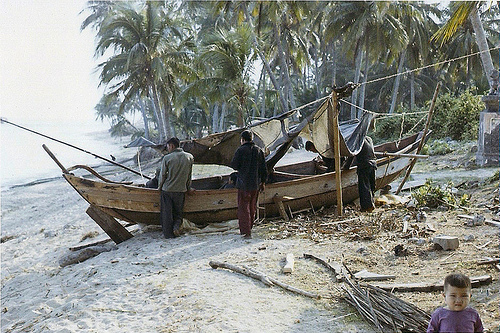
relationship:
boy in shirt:
[421, 275, 491, 328] [432, 308, 477, 331]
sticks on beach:
[341, 282, 416, 331] [0, 116, 134, 331]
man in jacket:
[231, 130, 269, 239] [227, 140, 269, 191]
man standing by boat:
[344, 134, 378, 212] [40, 126, 434, 230]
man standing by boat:
[229, 128, 271, 236] [40, 126, 434, 230]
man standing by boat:
[154, 136, 195, 239] [40, 126, 434, 230]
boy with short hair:
[423, 273, 484, 332] [444, 272, 471, 288]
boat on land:
[47, 77, 447, 244] [0, 208, 497, 330]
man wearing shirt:
[229, 128, 271, 236] [225, 140, 272, 190]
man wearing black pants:
[158, 137, 195, 239] [156, 183, 187, 241]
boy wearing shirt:
[423, 273, 484, 332] [425, 307, 484, 330]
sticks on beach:
[326, 261, 416, 331] [1, 14, 481, 321]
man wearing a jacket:
[231, 130, 269, 239] [229, 141, 268, 191]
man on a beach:
[158, 137, 195, 239] [0, 125, 497, 331]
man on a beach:
[231, 130, 269, 239] [0, 125, 497, 331]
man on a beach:
[344, 134, 378, 212] [0, 125, 497, 331]